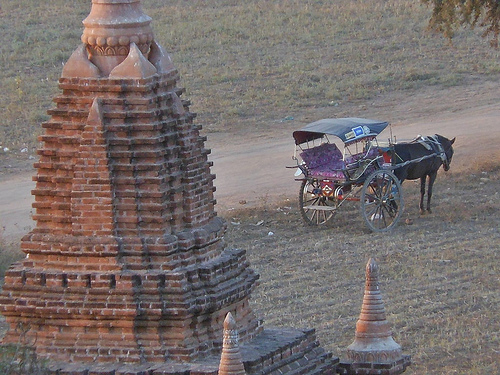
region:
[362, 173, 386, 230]
right wheel on wagon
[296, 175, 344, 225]
left wheel on wagon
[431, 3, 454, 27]
green grass on ground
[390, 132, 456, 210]
horse in front of carriage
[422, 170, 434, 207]
front right leg of horse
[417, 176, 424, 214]
front left leg of horse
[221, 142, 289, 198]
dirt road on the ground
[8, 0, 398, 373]
monument in background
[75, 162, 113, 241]
bricks on the monument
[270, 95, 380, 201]
a cart being pulled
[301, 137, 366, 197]
a purple cart interior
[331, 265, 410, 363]
a pointing building part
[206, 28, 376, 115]
ground is all dirt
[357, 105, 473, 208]
a mule is black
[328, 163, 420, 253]
large wooden wheels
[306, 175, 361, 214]
red on the cart bottom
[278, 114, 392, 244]
the carriage is empty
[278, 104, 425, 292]
the carriage is empty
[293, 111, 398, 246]
the carriage is empty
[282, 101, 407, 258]
the carriage is empty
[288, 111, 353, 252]
the carriage is empty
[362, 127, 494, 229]
the horse is brown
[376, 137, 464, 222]
the horse is brown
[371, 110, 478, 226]
the horse is brown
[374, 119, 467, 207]
the horse is brown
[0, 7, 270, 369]
A small structure made of red bricks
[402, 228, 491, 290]
Short green grass grows on the ground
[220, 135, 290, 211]
A dirt path on the ground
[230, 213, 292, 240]
Small pieces of litter on the ground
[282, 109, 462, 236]
A horse drawn carriage by the road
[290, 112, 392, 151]
A grey covering on the carriage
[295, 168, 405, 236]
Two thin wheels on the carriage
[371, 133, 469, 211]
A brown horse pulling the carriage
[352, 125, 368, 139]
A small blue logo on the carriage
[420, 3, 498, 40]
The brown leaves of a tree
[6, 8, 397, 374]
A large stone statue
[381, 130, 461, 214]
A black horse resting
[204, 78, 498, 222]
Horse on the side of the road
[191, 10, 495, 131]
Grassy area near a roadway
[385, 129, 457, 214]
black horse attached to the buggy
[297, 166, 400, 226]
wheels on the buggy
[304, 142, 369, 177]
purple cushion on the buggy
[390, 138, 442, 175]
harness on the horse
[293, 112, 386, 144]
canopy on the buggy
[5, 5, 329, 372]
brick statue near the buggy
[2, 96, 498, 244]
dirt path beside the buggy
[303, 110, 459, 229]
horse and buggy on the grass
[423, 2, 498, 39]
leaves hanging over the grass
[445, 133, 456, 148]
ear of the horse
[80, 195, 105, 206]
red brick in the ornate tower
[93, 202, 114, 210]
red brick in the ornate tower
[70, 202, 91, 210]
red brick in the ornate tower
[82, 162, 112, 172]
red brick in the ornate tower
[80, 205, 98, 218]
red brick in the ornate tower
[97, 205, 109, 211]
red brick in the ornate tower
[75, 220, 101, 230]
red brick in the ornate tower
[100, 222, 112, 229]
red brick in the ornate tower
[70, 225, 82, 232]
red brick in the ornate tower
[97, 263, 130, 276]
red brick in the ornate tower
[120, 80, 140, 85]
the brick is red